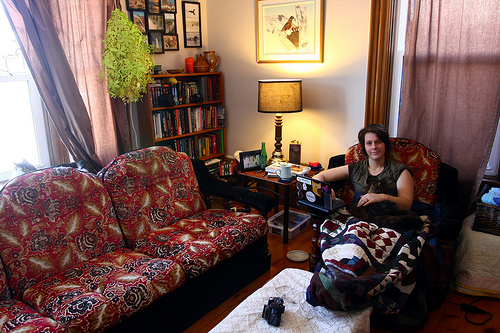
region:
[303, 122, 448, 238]
woman sitting in chair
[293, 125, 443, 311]
woman in chair with blanket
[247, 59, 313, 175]
standing lamp on end table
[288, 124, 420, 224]
woman with laptop in chair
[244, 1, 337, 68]
framed picture of birds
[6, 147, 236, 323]
red and black floral sofa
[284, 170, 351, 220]
laptop with several stickers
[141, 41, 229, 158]
fully stacked bookshelf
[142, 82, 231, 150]
collection of books on shelf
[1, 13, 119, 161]
mauve window curtain shade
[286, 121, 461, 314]
a woman in a chair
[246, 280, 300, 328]
black camera on a stool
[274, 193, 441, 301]
quilt over legs of woman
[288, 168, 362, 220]
a laptop open in front of woman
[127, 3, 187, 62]
a collague of pictures on the wall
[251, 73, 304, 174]
a table lamp with brown shade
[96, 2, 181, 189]
a tree by the window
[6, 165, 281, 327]
a red and black couch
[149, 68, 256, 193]
a book shelf with lots of books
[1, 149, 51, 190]
a cats head by the window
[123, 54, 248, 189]
books in the bookshelf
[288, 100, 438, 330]
a woman sitting on the chair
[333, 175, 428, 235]
a cat on woman's lap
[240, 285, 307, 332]
camera on the table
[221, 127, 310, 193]
picture frame on the side table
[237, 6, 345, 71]
painting on the wall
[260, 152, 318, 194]
the cup is white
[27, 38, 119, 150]
the curtain is brown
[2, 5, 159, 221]
the curtain is drawn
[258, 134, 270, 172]
the bottle is green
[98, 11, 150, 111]
green hanging fern plant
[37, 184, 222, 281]
sofa with a crazy pattern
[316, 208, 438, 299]
quilt on a woman's lap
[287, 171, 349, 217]
small laptop turned on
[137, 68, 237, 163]
wooden book shelf covered with books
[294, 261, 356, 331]
feet propped up on an ottoman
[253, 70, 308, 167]
illimunated table lamp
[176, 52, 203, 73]
red candle on top of the book shelf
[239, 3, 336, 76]
wall art above the lamp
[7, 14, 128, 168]
opened window curtains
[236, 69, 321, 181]
table lamp on table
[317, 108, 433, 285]
lady sitting on chair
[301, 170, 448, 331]
multi colored throw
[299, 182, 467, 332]
lady covering with multi color throw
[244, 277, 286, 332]
black camera on table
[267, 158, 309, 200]
white cup on table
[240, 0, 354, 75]
picture frame on wall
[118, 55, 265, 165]
book shelf against wall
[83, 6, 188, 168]
pot plant in living room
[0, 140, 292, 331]
red floral couch in living room